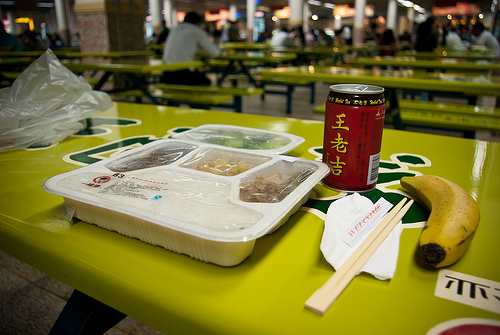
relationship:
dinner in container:
[56, 125, 321, 233] [38, 120, 337, 269]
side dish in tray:
[188, 125, 289, 150] [169, 123, 308, 154]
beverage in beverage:
[320, 80, 388, 194] [320, 80, 388, 194]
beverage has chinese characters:
[320, 80, 388, 194] [325, 154, 350, 176]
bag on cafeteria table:
[1, 44, 118, 155] [2, 100, 500, 333]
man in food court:
[159, 9, 226, 89] [2, 1, 499, 334]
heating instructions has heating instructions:
[92, 172, 164, 201] [92, 172, 164, 201]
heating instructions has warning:
[92, 172, 164, 201] [92, 170, 112, 188]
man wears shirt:
[159, 9, 226, 89] [159, 22, 227, 67]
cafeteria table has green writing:
[2, 100, 500, 333] [25, 113, 436, 232]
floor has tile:
[2, 57, 499, 334] [1, 263, 135, 334]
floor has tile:
[2, 57, 499, 334] [1, 248, 49, 307]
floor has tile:
[2, 57, 499, 334] [31, 274, 81, 301]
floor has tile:
[2, 57, 499, 334] [98, 324, 128, 334]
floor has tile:
[2, 57, 499, 334] [113, 314, 167, 334]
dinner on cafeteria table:
[56, 125, 321, 233] [2, 95, 498, 334]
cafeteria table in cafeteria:
[2, 100, 500, 333] [1, 1, 499, 334]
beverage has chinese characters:
[320, 80, 388, 194] [325, 109, 354, 183]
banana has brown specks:
[397, 170, 486, 276] [419, 189, 479, 250]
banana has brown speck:
[397, 170, 486, 276] [445, 245, 454, 254]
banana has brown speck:
[397, 170, 486, 276] [446, 199, 451, 204]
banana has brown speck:
[397, 170, 486, 276] [435, 177, 440, 182]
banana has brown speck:
[397, 170, 486, 276] [464, 210, 469, 216]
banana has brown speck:
[397, 170, 486, 276] [457, 235, 464, 240]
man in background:
[159, 9, 226, 89] [3, 1, 499, 116]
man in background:
[441, 25, 470, 53] [3, 1, 499, 116]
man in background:
[468, 20, 499, 52] [3, 1, 499, 116]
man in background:
[0, 20, 29, 57] [3, 1, 499, 116]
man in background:
[268, 25, 295, 48] [3, 1, 499, 116]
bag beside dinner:
[1, 44, 118, 155] [56, 125, 321, 233]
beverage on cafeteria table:
[320, 80, 388, 194] [2, 100, 500, 333]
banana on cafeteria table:
[397, 170, 486, 276] [2, 100, 500, 333]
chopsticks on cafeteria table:
[301, 195, 418, 318] [2, 100, 500, 333]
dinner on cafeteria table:
[56, 125, 321, 233] [2, 100, 500, 333]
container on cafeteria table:
[38, 120, 337, 269] [2, 100, 500, 333]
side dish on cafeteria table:
[188, 125, 289, 150] [2, 100, 500, 333]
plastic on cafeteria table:
[1, 44, 118, 155] [2, 100, 500, 333]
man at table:
[159, 9, 226, 89] [147, 47, 306, 101]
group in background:
[0, 1, 499, 54] [3, 1, 499, 116]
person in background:
[370, 12, 398, 46] [3, 1, 499, 116]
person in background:
[412, 13, 446, 54] [3, 1, 499, 116]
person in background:
[331, 26, 347, 50] [3, 1, 499, 116]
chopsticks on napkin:
[301, 195, 418, 318] [317, 190, 406, 284]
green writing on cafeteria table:
[25, 113, 436, 232] [2, 100, 500, 333]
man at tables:
[468, 20, 499, 52] [394, 40, 499, 59]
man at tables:
[268, 25, 295, 48] [222, 40, 383, 57]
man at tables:
[0, 20, 29, 57] [0, 47, 88, 63]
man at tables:
[159, 9, 226, 89] [143, 39, 274, 51]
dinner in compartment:
[56, 125, 321, 233] [100, 138, 200, 175]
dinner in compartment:
[56, 125, 321, 233] [234, 156, 329, 206]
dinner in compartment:
[56, 125, 321, 233] [43, 164, 272, 273]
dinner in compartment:
[56, 125, 321, 233] [169, 144, 282, 181]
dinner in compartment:
[56, 125, 321, 233] [169, 124, 307, 155]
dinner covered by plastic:
[56, 125, 321, 233] [40, 122, 331, 244]